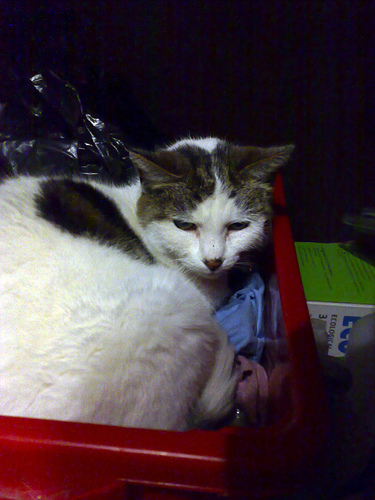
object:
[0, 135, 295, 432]
cat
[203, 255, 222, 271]
nose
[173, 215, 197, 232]
eye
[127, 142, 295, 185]
ears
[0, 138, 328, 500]
box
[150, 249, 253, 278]
whiskers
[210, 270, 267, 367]
cloth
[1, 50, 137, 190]
bag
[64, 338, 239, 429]
tail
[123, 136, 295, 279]
head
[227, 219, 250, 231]
eyes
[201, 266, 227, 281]
mouth